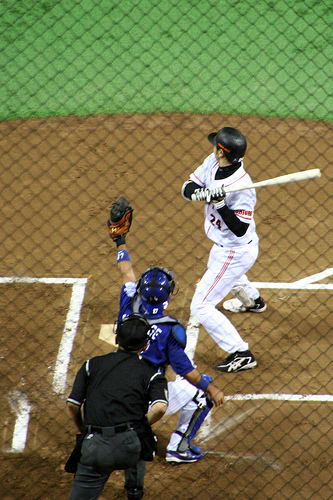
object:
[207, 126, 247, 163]
helmet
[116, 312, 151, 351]
hat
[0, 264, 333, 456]
markings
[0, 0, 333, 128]
field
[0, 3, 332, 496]
fence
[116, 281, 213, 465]
uniform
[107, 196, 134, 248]
catcher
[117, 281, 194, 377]
jersey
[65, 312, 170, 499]
umpire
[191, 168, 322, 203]
bat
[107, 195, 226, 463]
catcher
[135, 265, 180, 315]
gear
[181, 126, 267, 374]
batter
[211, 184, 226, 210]
gloves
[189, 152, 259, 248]
jersey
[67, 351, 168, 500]
clothing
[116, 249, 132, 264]
armband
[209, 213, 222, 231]
number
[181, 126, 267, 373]
man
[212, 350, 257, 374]
foot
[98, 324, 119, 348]
base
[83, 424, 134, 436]
belt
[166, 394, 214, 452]
shinguard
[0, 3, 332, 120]
grass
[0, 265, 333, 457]
lines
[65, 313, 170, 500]
black